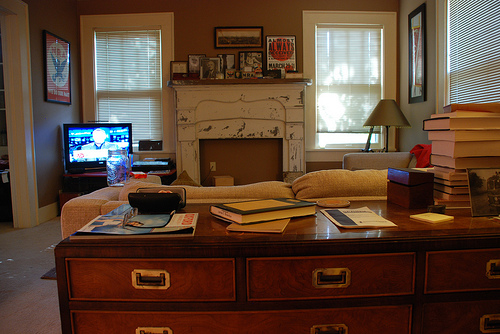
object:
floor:
[0, 215, 59, 334]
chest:
[55, 203, 499, 333]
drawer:
[67, 258, 235, 302]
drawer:
[246, 253, 415, 302]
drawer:
[425, 248, 500, 293]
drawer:
[70, 306, 412, 334]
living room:
[0, 0, 499, 334]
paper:
[320, 206, 398, 228]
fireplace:
[200, 138, 283, 187]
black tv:
[63, 123, 132, 174]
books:
[427, 130, 499, 140]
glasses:
[122, 208, 174, 229]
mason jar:
[106, 148, 130, 187]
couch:
[61, 167, 433, 239]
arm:
[63, 175, 161, 206]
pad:
[427, 205, 445, 214]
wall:
[28, 0, 82, 209]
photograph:
[215, 28, 261, 47]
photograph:
[189, 55, 205, 73]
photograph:
[239, 53, 262, 77]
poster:
[46, 34, 70, 102]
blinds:
[314, 25, 381, 133]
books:
[432, 141, 500, 157]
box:
[387, 168, 434, 209]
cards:
[409, 213, 454, 224]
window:
[94, 30, 162, 152]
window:
[315, 24, 383, 145]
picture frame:
[46, 34, 70, 103]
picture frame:
[216, 28, 262, 47]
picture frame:
[408, 3, 427, 103]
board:
[247, 252, 416, 300]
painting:
[411, 12, 421, 98]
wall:
[174, 1, 304, 72]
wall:
[400, 0, 436, 152]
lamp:
[363, 99, 411, 152]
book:
[70, 213, 199, 240]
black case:
[128, 187, 187, 211]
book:
[208, 198, 316, 226]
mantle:
[175, 83, 305, 137]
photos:
[172, 62, 188, 79]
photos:
[200, 58, 220, 77]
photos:
[218, 55, 235, 79]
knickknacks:
[285, 73, 302, 79]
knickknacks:
[262, 75, 273, 79]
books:
[423, 116, 500, 131]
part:
[246, 257, 312, 301]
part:
[317, 271, 346, 285]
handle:
[312, 267, 351, 288]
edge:
[241, 204, 316, 224]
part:
[325, 210, 357, 225]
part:
[57, 203, 207, 247]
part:
[223, 199, 295, 211]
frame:
[81, 11, 176, 153]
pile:
[209, 199, 317, 234]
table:
[62, 169, 176, 192]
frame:
[0, 0, 38, 228]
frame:
[266, 35, 297, 71]